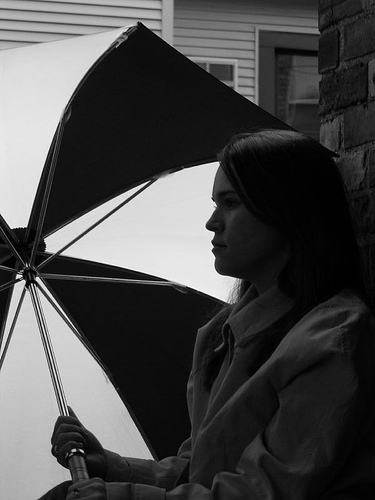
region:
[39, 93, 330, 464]
woman holding umbrella to her side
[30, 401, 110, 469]
hand wrapped around umbrella handle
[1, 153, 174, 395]
dark and light umbrella panels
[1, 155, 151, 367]
metal rods pointing outwards from center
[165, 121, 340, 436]
woman seated with raincoat on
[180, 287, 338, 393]
collar of jacket open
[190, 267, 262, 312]
strands of hair under chin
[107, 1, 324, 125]
clapboard house behind umbrella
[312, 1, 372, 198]
brick wall behind head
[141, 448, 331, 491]
folds of fabric on sleeves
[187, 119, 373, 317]
Lady with Determined Look on her face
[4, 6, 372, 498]
Lady with Umbrella to protect her from the rain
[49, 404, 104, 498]
She has at least 2 rings on her fingers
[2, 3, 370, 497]
Umbrella is really large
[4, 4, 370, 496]
Umbrella is large enough for 2 people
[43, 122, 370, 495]
Lady is wearing a rain coat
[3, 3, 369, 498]
Lady is sitting against bricks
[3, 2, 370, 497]
Lady is sitting close to house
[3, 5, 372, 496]
This photo is black and white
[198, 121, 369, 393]
Lady with long dark hair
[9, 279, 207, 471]
umbrella is black and white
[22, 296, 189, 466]
umbrella is black and white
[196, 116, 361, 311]
Woman staring to the left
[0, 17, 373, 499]
Woman sitting holding an umbrella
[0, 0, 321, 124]
A shingled house in the background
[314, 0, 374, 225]
A brick wall behind the woman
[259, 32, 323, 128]
Part of a door of the house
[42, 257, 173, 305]
A silver spoke of the umbrella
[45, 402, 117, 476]
The woman's hand curled around the umbrella stick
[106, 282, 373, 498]
Woman wearing a jacket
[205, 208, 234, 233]
The woman's nose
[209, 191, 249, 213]
The woman's eye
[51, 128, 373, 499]
a beautiful young lady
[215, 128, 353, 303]
beautiful black long hair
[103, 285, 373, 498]
long sleeve gray coat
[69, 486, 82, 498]
a silver finger ring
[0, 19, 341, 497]
black and white umbrella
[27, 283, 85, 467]
a chrome metal rod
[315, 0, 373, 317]
gray and white brick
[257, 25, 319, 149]
a black and white glass door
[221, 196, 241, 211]
beautiful black and white eye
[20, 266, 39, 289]
a small black plastic piece